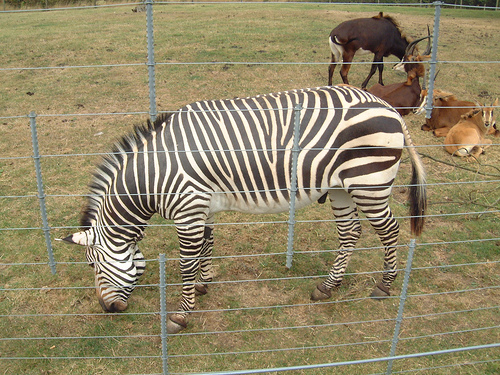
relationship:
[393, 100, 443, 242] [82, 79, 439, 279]
tail of zebra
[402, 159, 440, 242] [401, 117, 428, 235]
hair on tail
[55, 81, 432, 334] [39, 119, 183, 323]
zebra has head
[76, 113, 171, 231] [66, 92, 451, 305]
mane on zebra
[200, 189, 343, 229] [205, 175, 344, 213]
white under belly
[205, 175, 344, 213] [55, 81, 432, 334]
belly of zebra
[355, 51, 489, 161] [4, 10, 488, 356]
animals laying on grass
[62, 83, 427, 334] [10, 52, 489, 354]
zebra eating grass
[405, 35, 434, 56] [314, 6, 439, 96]
horn on animal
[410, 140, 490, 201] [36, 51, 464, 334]
sticks on ground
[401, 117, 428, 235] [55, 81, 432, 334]
tail on zebra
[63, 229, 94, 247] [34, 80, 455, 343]
ear on zebra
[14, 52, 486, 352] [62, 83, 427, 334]
fence in front of zebra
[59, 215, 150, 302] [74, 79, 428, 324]
head of zebra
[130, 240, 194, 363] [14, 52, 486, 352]
metal on fence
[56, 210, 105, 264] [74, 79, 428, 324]
ear of zebra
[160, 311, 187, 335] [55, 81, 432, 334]
hoof of a zebra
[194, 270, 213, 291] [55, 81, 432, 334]
hoof of a zebra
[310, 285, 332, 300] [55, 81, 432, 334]
hoof of a zebra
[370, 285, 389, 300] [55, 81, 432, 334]
hoof of a zebra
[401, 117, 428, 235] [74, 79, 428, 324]
tail of a zebra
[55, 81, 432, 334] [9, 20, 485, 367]
zebra standing behind a fence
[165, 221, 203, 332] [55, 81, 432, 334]
leg of a zebra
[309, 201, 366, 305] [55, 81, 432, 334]
leg of a zebra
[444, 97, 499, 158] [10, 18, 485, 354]
animal laying on ground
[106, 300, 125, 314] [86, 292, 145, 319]
mouth eating grass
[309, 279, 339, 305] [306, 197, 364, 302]
hoof on leg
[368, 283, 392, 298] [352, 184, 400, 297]
hoof on leg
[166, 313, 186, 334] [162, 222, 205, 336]
hoof attached to leg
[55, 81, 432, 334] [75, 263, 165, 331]
zebra eating grass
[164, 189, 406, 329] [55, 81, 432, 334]
legs of a zebra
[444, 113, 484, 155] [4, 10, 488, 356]
animal sitting on grass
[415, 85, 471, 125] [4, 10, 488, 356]
animal sitting on grass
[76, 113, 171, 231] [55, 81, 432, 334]
mane of a zebra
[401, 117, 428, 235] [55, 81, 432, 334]
tail of zebra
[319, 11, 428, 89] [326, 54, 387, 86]
animal has legs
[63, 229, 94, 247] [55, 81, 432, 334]
ear of a zebra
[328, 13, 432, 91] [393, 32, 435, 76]
animal with head down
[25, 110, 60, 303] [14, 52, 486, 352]
bar on fence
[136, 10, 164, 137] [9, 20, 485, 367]
bar on fence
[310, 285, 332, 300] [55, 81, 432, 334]
hoof of zebra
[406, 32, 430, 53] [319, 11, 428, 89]
horn of animal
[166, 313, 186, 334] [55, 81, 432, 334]
hoof of zebra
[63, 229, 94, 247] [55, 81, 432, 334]
ear of zebra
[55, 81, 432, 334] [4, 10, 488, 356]
zebra eating grass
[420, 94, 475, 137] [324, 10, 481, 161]
animal of animals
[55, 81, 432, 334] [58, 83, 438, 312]
zebra has stripes